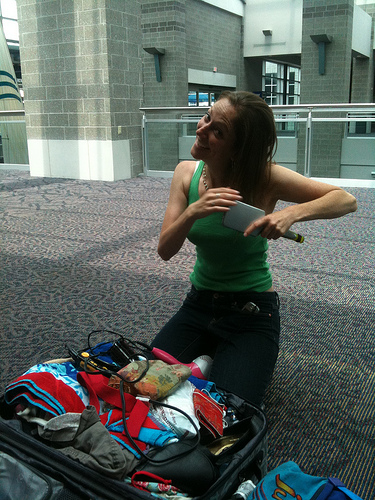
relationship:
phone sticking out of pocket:
[240, 299, 263, 313] [233, 300, 273, 328]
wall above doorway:
[184, 3, 243, 83] [187, 82, 232, 105]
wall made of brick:
[111, 5, 143, 174] [113, 56, 129, 70]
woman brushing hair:
[155, 91, 358, 393] [221, 90, 279, 191]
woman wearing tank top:
[155, 91, 358, 393] [185, 156, 273, 290]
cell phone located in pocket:
[240, 299, 263, 313] [233, 300, 273, 328]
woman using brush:
[155, 91, 358, 393] [223, 201, 306, 243]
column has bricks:
[14, 1, 145, 173] [21, 4, 58, 33]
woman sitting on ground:
[155, 91, 358, 393] [3, 166, 374, 495]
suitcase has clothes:
[1, 346, 266, 496] [75, 412, 132, 474]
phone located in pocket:
[240, 299, 263, 313] [233, 300, 273, 328]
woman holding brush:
[155, 91, 358, 393] [223, 201, 306, 243]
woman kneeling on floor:
[155, 91, 358, 393] [3, 166, 374, 495]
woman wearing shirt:
[155, 91, 358, 393] [185, 156, 273, 290]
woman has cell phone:
[155, 91, 358, 393] [240, 299, 263, 313]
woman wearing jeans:
[155, 91, 358, 393] [152, 288, 282, 396]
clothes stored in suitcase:
[75, 412, 132, 474] [1, 346, 266, 496]